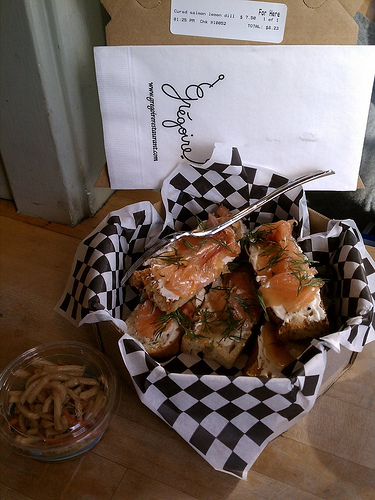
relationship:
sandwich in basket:
[246, 219, 329, 336] [110, 189, 364, 404]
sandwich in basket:
[183, 269, 260, 361] [110, 189, 364, 404]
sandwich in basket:
[135, 212, 252, 314] [110, 189, 364, 404]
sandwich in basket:
[126, 297, 179, 357] [110, 189, 364, 404]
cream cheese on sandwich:
[271, 291, 325, 323] [246, 219, 329, 336]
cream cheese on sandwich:
[156, 280, 181, 307] [135, 212, 252, 314]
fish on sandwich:
[250, 218, 325, 312] [246, 219, 329, 336]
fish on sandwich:
[156, 207, 241, 297] [135, 212, 252, 314]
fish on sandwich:
[208, 272, 261, 341] [183, 269, 260, 361]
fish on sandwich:
[138, 298, 169, 335] [126, 297, 179, 357]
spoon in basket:
[120, 170, 340, 286] [110, 189, 364, 404]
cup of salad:
[0, 337, 117, 462] [8, 356, 104, 437]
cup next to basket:
[0, 337, 117, 462] [110, 189, 364, 404]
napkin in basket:
[52, 142, 374, 482] [110, 189, 364, 404]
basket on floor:
[110, 189, 364, 404] [0, 186, 375, 499]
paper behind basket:
[91, 45, 375, 191] [110, 189, 364, 404]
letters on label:
[173, 8, 282, 31] [169, 0, 287, 44]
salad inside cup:
[8, 356, 104, 437] [0, 337, 117, 462]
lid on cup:
[3, 339, 121, 457] [0, 337, 117, 462]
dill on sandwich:
[245, 229, 331, 296] [246, 219, 329, 336]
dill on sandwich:
[149, 250, 191, 269] [135, 212, 252, 314]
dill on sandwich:
[150, 309, 193, 337] [126, 297, 179, 357]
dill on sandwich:
[213, 306, 247, 346] [183, 269, 260, 361]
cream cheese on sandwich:
[221, 257, 234, 265] [135, 212, 252, 314]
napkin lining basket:
[52, 142, 374, 482] [110, 189, 364, 404]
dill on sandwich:
[208, 233, 236, 253] [135, 212, 252, 314]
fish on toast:
[250, 218, 325, 312] [271, 308, 333, 344]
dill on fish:
[245, 229, 331, 296] [250, 218, 325, 312]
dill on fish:
[208, 233, 236, 253] [156, 207, 241, 297]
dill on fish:
[149, 250, 191, 269] [156, 207, 241, 297]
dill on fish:
[150, 309, 193, 337] [138, 298, 169, 335]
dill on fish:
[213, 306, 247, 346] [208, 272, 261, 341]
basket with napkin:
[110, 189, 364, 404] [52, 142, 374, 482]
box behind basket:
[100, 1, 374, 45] [110, 189, 364, 404]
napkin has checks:
[52, 142, 374, 482] [169, 172, 191, 190]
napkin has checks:
[52, 142, 374, 482] [193, 177, 213, 198]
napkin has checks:
[52, 142, 374, 482] [215, 180, 237, 198]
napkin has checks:
[52, 142, 374, 482] [178, 192, 192, 206]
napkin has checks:
[52, 142, 374, 482] [132, 210, 147, 228]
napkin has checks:
[52, 142, 374, 482] [204, 185, 225, 203]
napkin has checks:
[52, 142, 374, 482] [226, 174, 247, 188]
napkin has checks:
[52, 142, 374, 482] [252, 168, 273, 185]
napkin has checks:
[52, 142, 374, 482] [200, 391, 229, 411]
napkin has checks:
[52, 142, 374, 482] [230, 393, 260, 411]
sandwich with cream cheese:
[135, 212, 252, 314] [156, 280, 181, 307]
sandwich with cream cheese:
[135, 212, 252, 314] [221, 257, 234, 265]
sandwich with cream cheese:
[246, 219, 329, 336] [271, 291, 325, 323]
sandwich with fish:
[135, 212, 252, 314] [156, 207, 241, 297]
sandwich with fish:
[126, 297, 179, 357] [138, 298, 169, 335]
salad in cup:
[8, 356, 104, 437] [0, 337, 117, 462]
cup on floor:
[0, 337, 117, 462] [0, 186, 375, 499]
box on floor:
[100, 1, 374, 45] [0, 186, 375, 499]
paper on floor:
[91, 45, 375, 191] [0, 186, 375, 499]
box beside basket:
[100, 1, 374, 45] [110, 189, 364, 404]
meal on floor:
[4, 180, 374, 462] [0, 186, 375, 499]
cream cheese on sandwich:
[249, 240, 259, 267] [246, 219, 329, 336]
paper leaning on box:
[91, 45, 375, 191] [100, 1, 374, 45]